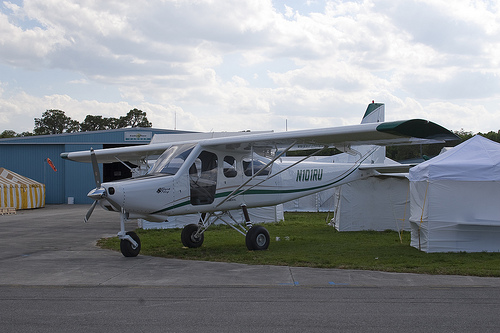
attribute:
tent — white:
[409, 133, 499, 251]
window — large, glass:
[133, 140, 195, 180]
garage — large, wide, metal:
[0, 125, 203, 205]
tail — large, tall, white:
[341, 110, 417, 180]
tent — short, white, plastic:
[405, 130, 499, 258]